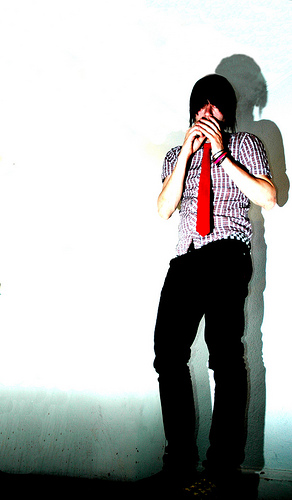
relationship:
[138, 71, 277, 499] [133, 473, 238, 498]
boy has shoes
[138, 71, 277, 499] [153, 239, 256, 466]
boy has pants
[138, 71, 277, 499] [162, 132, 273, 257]
boy has shirt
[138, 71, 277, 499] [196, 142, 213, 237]
boy has tie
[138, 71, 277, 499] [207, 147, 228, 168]
boy has bracelets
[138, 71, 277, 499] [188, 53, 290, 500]
boy has shadow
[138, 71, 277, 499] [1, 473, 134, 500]
boy standing on floor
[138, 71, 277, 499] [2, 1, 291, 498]
boy leaning against wall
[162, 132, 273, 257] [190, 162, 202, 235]
shirt has buttons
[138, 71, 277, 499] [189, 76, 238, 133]
boy has hair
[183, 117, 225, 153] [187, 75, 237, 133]
hands over head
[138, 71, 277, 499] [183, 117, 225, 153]
boy has hands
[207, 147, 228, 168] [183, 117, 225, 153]
bracelets are on hands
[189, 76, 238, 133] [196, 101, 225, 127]
hair covering face